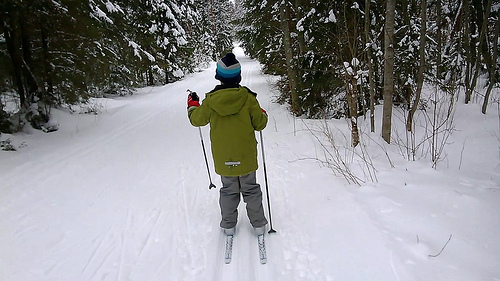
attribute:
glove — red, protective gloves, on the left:
[184, 87, 213, 116]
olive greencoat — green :
[186, 85, 268, 176]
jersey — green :
[191, 83, 271, 178]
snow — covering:
[27, 100, 111, 169]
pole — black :
[189, 90, 218, 189]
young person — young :
[182, 50, 277, 244]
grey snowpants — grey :
[212, 168, 269, 233]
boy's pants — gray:
[208, 172, 290, 209]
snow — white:
[1, 42, 499, 279]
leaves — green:
[360, 60, 370, 79]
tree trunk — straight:
[382, 4, 399, 154]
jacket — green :
[185, 85, 273, 177]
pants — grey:
[183, 162, 287, 235]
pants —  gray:
[220, 169, 269, 229]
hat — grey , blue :
[210, 52, 245, 89]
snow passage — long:
[127, 58, 262, 267]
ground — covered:
[1, 42, 498, 279]